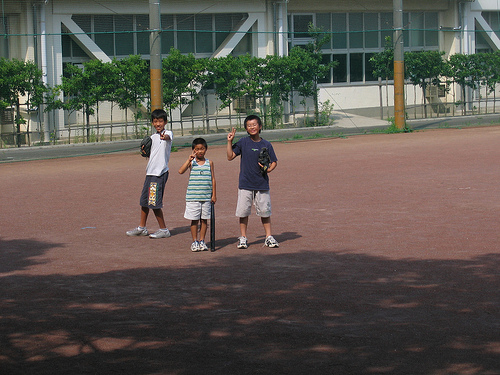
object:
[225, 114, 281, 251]
boy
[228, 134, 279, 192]
shirt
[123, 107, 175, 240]
boy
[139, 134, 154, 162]
mitt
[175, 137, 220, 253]
boy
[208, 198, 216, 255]
bat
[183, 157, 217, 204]
shirt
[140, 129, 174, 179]
shirt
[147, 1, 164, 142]
pole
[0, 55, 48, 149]
tree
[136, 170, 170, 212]
shorts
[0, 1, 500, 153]
building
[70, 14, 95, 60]
window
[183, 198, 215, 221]
shorts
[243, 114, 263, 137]
hair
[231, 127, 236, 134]
two fingers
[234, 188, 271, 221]
shorts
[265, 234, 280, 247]
shoe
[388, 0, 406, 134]
pole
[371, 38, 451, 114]
tree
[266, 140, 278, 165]
sleeve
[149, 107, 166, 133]
head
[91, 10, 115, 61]
window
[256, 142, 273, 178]
glove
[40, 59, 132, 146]
tree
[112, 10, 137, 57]
window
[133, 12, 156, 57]
window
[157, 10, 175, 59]
window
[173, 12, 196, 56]
window